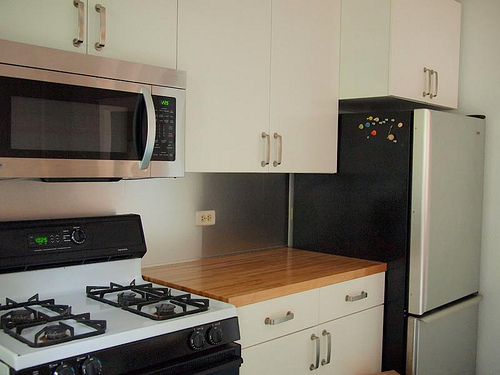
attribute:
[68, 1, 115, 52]
handles — metal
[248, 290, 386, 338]
drawers — kitchen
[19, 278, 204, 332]
stove — top, black, gas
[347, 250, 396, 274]
counter — wooden, wood, empty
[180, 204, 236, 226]
outlet — electrical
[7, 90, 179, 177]
microwave — black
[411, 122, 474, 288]
refrigerator — black, stainless steel, huge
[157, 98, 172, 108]
numbers — green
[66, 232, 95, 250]
range — gas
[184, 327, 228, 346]
knobs — black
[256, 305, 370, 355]
cabinets — white